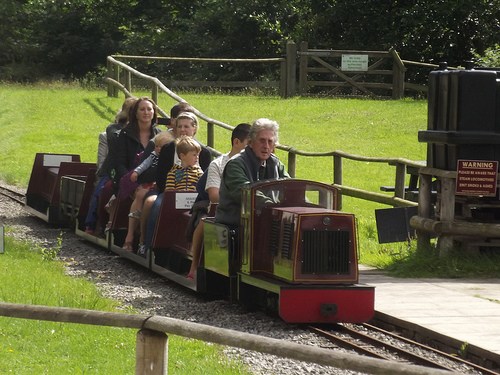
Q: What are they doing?
A: Sitting.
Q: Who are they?
A: People.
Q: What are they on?
A: Mini train.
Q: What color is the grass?
A: Green.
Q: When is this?
A: Daytime.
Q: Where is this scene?
A: Outside in the park.